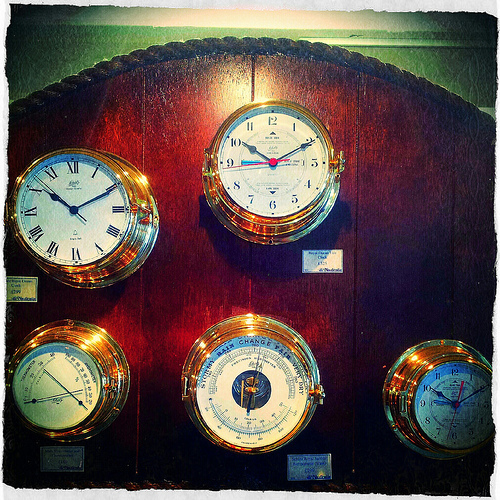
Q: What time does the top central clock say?
A: 10:11.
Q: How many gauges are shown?
A: 5.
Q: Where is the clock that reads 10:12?
A: Top left side.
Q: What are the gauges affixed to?
A: Wood.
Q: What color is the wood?
A: Reddish brown.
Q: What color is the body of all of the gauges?
A: Golden.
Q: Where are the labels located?
A: Under each gauge.